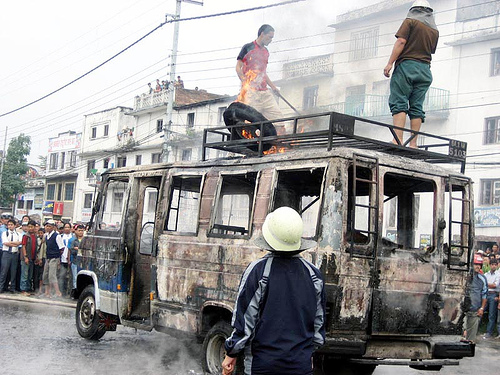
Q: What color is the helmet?
A: White.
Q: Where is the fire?
A: On the vehicle.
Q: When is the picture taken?
A: Daytime.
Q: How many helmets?
A: Two.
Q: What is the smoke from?
A: The fire.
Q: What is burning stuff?
A: Fire.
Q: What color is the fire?
A: Orange.